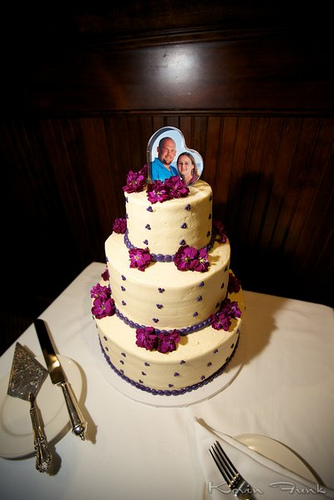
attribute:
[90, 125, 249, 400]
cake — wedding cake, anniversary cake, wedding case, white, purple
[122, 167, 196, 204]
flowers — purple, decoration, decorative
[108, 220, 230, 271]
flowers — purple, decoration, decorative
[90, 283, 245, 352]
flowers — purple, decoration, decorative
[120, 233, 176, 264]
trim — purple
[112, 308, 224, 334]
trim — purple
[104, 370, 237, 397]
trim — purple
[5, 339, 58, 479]
cake server — silver, decorative, ornate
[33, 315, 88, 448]
cake knife — silver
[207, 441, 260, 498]
fork — silver, metal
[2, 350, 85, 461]
plate — ceramic, white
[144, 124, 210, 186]
heart — glass, blue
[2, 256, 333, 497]
table cloth — white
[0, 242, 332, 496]
table — white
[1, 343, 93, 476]
dish — white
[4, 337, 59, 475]
spatula — silver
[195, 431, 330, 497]
napkin — dinner napkin, white, folded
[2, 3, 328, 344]
wall — brown, wood, paneled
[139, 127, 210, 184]
frame — silver, heart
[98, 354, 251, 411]
plate — round, circular